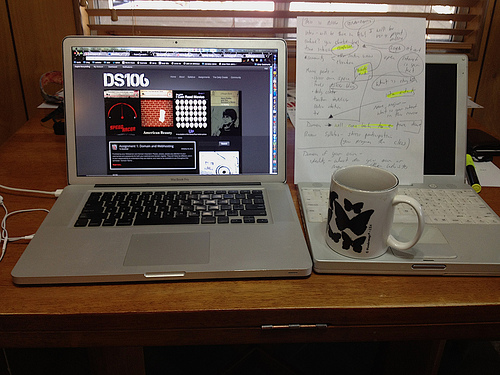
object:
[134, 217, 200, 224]
black keys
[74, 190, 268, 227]
keyboard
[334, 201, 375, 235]
drawing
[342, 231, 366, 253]
drawing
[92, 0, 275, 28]
window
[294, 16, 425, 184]
paper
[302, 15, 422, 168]
notes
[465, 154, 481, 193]
marker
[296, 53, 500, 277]
laptop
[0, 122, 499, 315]
surface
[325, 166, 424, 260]
b&w cup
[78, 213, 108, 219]
keys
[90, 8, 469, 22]
blinds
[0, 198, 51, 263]
cable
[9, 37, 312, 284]
computer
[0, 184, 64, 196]
cables